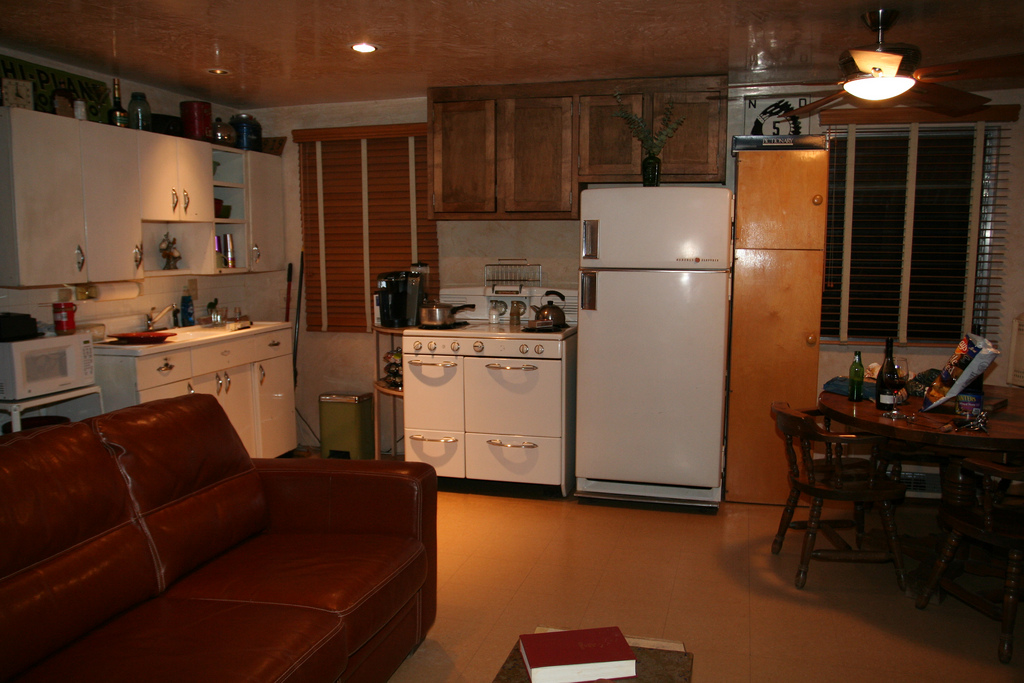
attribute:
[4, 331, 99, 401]
microwave — white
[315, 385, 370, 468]
bin — green, trash bin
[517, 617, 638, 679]
book — red 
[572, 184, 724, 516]
fridge — white 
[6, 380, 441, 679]
couch — red 